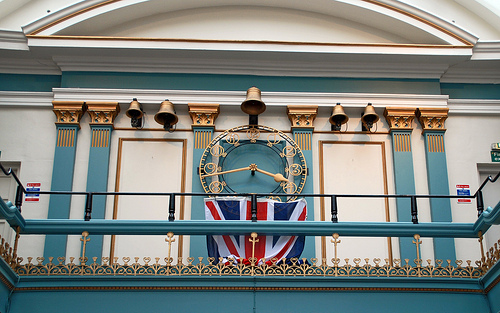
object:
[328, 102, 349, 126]
light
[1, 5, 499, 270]
wall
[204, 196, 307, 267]
flag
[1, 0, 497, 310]
building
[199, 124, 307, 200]
clock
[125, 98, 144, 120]
bell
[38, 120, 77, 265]
pillar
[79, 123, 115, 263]
pillar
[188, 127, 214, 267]
pillar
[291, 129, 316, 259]
pillar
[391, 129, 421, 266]
pillar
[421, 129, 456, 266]
pillar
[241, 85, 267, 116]
light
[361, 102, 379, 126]
light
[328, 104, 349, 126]
bell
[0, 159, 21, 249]
doorway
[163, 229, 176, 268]
decorative pillars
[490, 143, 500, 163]
sign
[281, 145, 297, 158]
2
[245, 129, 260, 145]
number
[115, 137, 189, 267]
decal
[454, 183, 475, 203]
sign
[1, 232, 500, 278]
decorative pattern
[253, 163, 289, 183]
hour hand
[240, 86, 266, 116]
bell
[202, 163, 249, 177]
hand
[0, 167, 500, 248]
railing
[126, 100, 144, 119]
light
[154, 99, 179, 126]
light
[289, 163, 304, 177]
number 3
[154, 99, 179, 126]
bell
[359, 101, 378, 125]
bell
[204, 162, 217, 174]
9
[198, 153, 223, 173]
metal-work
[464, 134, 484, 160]
lettering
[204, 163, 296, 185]
time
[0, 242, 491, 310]
area